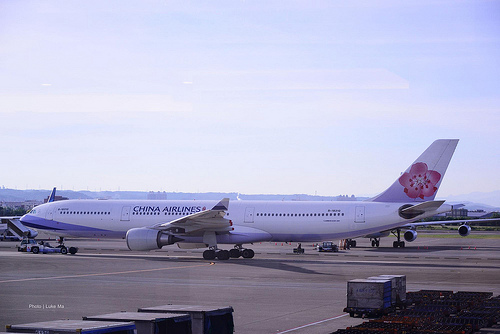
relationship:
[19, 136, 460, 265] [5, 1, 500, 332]
airplane at airport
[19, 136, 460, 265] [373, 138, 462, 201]
airplane has a tail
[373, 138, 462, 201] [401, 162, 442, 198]
tail has a flower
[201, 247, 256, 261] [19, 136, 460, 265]
wheels are under airplane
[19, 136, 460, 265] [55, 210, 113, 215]
airplane has windows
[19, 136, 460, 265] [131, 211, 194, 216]
airplane has windows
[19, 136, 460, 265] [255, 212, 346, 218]
airplane has windows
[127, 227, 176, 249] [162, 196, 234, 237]
engine on wing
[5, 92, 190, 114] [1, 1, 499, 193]
clouds are in sky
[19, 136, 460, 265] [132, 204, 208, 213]
airplane has a logo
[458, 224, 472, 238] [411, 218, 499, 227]
engine on wing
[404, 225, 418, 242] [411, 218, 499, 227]
engine on wing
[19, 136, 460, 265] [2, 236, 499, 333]
airplane on ground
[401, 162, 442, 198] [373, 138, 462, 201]
flower on tail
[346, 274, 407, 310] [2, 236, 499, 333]
cargo boxes are on ground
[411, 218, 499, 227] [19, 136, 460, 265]
wing behind airplane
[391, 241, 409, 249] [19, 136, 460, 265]
wheels behind airplane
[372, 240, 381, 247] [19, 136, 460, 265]
wheels behind airplane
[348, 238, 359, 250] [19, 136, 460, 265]
wheels behind airplane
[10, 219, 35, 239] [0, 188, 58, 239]
stairs for airplane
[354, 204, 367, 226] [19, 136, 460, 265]
emergency door on airplane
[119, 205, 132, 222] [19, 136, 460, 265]
door on airplane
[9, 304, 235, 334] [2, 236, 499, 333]
cargo boxes are on ground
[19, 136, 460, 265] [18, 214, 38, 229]
airplane has a nose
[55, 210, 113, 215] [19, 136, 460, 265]
windows are on airplane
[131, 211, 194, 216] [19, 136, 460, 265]
windows are on airplane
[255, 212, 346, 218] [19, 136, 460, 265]
windows are on airplane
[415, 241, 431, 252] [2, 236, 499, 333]
cones are on ground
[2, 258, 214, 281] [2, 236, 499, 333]
line on ground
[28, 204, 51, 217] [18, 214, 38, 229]
cockpit near nose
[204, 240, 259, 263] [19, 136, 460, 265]
landing gear under airplane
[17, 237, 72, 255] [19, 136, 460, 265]
vehicle near airplane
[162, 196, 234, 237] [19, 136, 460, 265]
wing on airplane